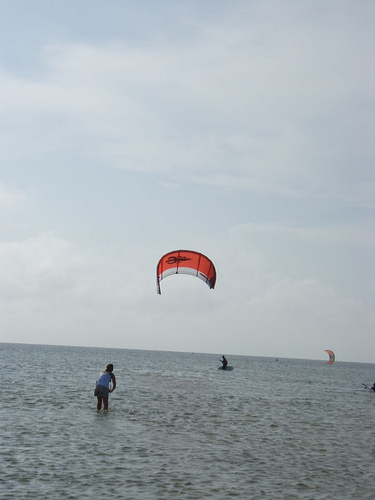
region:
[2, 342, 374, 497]
choppy and shallow large lake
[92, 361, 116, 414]
woman standing in lake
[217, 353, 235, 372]
man kneeling on skim board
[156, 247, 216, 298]
red and grey parasail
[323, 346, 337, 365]
orange and grey parasail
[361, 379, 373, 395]
long oar in kayak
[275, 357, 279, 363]
person swimming in lake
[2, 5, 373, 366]
clouds in blue sky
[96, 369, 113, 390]
white tankini swim top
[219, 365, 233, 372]
medium size black skim board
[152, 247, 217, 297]
red kite in sky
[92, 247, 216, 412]
person flying kite from water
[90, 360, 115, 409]
person standing in ocean water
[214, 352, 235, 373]
person on a surfboard in ocean water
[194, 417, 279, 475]
blue ocean water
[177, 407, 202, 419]
ripple in ocean water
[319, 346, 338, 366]
sail in ocean water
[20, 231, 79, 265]
grey cloud in sky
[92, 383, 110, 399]
person with beige shorts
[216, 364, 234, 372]
surfboard in ocean water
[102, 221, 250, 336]
red and white parasail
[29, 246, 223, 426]
person flying read and white parasail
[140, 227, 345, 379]
two parasails in water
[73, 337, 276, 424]
two people standing in water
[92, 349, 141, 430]
person in white tshirt in water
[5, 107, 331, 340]
mostly cloudy sky in photo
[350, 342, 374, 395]
something black on right hand side of photo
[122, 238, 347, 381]
one parasail closer to shre than other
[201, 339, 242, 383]
person with surfboard in water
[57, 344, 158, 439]
person leaning over in water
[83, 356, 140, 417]
person standing in water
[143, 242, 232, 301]
red and white parasail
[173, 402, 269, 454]
ripples on water surface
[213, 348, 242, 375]
person on para sail board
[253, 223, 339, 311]
white clouds in daytime sky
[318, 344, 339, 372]
parasail near water's surface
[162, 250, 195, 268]
black design on parasail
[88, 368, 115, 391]
white top on woman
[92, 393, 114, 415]
legs in water up to shins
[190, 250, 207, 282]
rod in parasail frame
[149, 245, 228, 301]
orange and white wind sail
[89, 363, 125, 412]
woman wading in the water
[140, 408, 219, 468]
ripples in the water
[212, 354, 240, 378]
person preparing to take off on wind sail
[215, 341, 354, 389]
person with orange and white wind sail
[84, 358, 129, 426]
girl in a white shirt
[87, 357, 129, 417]
blonde girl in khaki shorts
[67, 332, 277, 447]
two people getting ready to wind sail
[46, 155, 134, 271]
light blue sky with clouds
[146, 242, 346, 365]
two wind sails flying